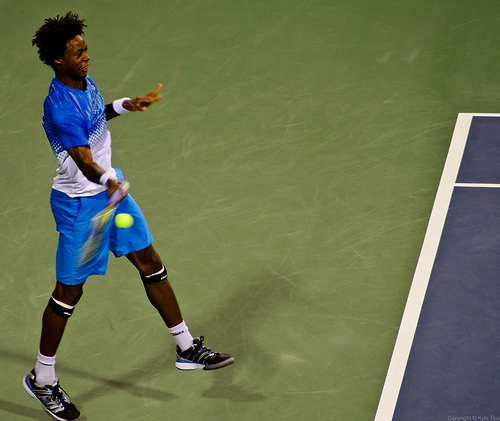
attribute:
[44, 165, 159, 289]
shorts — blue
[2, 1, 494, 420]
court — blue, green, purple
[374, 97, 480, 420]
line — white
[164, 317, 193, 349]
sock — white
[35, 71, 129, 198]
shirt — blue, white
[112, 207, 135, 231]
ball — bright, green, yellow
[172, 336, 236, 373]
shoe — black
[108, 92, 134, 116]
wrist band — white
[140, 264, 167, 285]
band — dark, black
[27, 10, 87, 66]
hair — unkempt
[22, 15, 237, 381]
man — holding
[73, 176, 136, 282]
racket — swinging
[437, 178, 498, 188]
line — white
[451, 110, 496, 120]
line — white